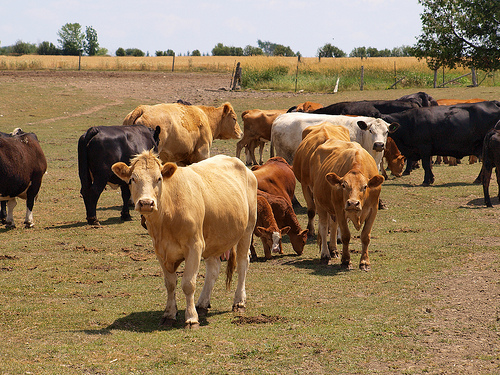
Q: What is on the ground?
A: Grass.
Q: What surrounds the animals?
A: A fence.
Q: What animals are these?
A: Cows.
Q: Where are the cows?
A: In a pasture.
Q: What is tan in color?
A: The cow.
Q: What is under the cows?
A: Grass and dirt.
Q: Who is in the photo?
A: No people.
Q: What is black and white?
A: Some animals.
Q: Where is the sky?
A: Above the land.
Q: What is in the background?
A: Trees.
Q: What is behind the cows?
A: The fence.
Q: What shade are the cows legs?
A: White.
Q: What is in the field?
A: Grass and dirt.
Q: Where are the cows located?
A: In the pasture.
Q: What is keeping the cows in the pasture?
A: A fence.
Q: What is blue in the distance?
A: The sky.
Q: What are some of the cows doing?
A: Grazing.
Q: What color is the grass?
A: Green.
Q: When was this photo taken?
A: During the day.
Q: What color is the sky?
A: Light blue.